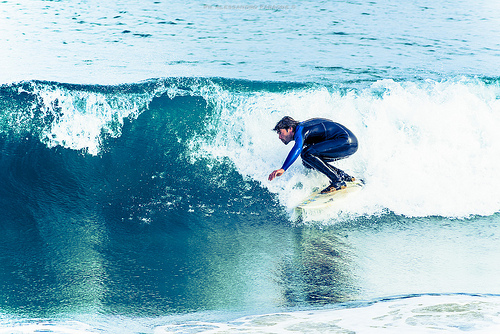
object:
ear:
[288, 124, 295, 134]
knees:
[298, 149, 318, 160]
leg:
[301, 139, 343, 182]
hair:
[273, 114, 301, 130]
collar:
[292, 121, 299, 137]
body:
[267, 118, 359, 194]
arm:
[278, 128, 303, 171]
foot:
[320, 181, 345, 193]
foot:
[335, 173, 355, 183]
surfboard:
[295, 177, 365, 208]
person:
[267, 114, 359, 195]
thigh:
[301, 138, 343, 160]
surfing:
[266, 115, 367, 212]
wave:
[0, 76, 500, 225]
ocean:
[0, 0, 498, 333]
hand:
[267, 167, 283, 182]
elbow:
[292, 144, 303, 153]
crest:
[0, 76, 500, 227]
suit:
[278, 116, 357, 186]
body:
[93, 15, 314, 86]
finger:
[271, 170, 279, 179]